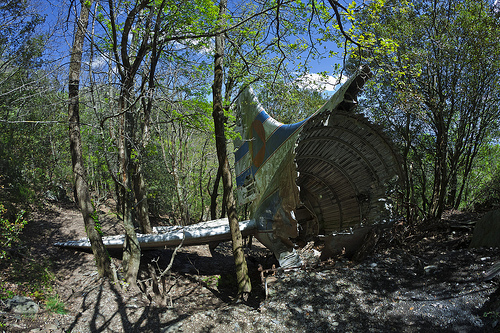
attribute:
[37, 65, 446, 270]
airplane — broken, blue, white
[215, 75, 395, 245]
plane — broken, circular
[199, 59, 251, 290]
tree trunk — tall, brown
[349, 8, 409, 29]
leaves — green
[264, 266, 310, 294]
dirt — brown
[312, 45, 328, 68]
sky — blue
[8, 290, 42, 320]
rock — grey